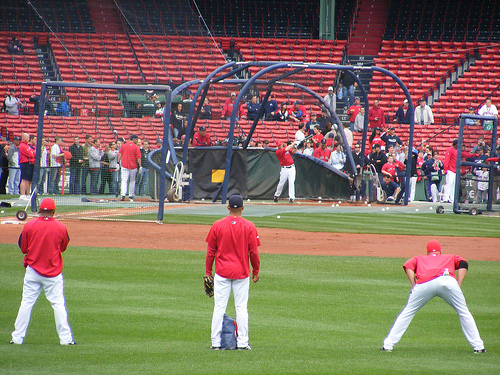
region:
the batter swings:
[268, 132, 313, 200]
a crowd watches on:
[10, 130, 159, 196]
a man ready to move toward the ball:
[377, 245, 477, 348]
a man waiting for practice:
[199, 186, 261, 359]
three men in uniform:
[4, 175, 452, 373]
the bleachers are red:
[68, 25, 230, 108]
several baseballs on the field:
[202, 193, 438, 229]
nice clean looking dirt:
[79, 211, 354, 276]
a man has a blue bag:
[210, 310, 247, 352]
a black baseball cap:
[226, 190, 250, 212]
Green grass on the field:
[92, 267, 173, 353]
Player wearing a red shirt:
[201, 192, 267, 290]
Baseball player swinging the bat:
[260, 129, 316, 203]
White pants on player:
[4, 257, 82, 359]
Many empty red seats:
[58, 30, 212, 80]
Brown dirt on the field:
[78, 218, 154, 247]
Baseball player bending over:
[390, 236, 487, 360]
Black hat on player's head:
[219, 188, 251, 219]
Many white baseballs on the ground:
[300, 185, 443, 224]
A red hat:
[33, 195, 58, 223]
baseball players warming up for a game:
[10, 18, 484, 355]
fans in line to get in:
[46, 135, 121, 182]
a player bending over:
[378, 226, 497, 361]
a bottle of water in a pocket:
[441, 262, 458, 278]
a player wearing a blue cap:
[194, 185, 283, 359]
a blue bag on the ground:
[214, 312, 242, 349]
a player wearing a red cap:
[15, 187, 97, 347]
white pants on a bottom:
[11, 270, 76, 345]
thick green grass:
[279, 280, 344, 355]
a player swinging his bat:
[268, 102, 320, 219]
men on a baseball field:
[3, 142, 498, 371]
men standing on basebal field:
[35, 161, 492, 373]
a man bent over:
[343, 211, 485, 356]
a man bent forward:
[374, 203, 484, 371]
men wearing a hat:
[26, 163, 474, 373]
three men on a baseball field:
[20, 173, 489, 368]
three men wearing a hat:
[17, 157, 490, 364]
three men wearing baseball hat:
[12, 160, 475, 372]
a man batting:
[265, 96, 319, 199]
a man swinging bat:
[250, 97, 340, 192]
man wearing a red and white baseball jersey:
[12, 182, 99, 372]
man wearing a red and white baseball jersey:
[190, 180, 262, 356]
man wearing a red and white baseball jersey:
[373, 222, 487, 362]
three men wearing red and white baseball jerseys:
[11, 192, 484, 364]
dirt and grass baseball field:
[80, 197, 193, 359]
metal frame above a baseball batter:
[155, 45, 422, 209]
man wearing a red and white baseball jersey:
[259, 116, 339, 218]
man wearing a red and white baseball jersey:
[113, 131, 175, 208]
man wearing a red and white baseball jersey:
[427, 126, 480, 208]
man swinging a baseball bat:
[264, 127, 341, 209]